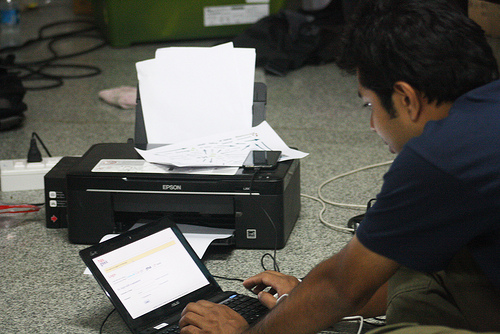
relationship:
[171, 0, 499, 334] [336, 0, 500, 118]
man has dark hair.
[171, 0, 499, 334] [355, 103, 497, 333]
man wearing shirt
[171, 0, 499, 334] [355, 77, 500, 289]
man wearing shirt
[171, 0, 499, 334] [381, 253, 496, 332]
man wearing pants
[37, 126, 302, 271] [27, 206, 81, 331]
printer sitting on floor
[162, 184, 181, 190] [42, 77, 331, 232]
logo on printer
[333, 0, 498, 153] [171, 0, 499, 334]
head of a man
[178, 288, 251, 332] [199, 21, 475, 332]
hand of a man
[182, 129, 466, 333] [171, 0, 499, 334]
arm of a man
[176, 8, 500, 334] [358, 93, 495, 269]
man wearing shirt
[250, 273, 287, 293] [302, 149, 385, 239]
mouse and cable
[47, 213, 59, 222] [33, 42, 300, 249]
light on printer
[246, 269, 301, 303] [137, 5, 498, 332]
hand of a man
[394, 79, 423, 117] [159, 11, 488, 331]
ear of a man